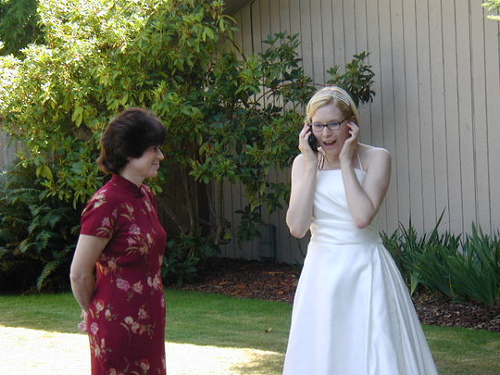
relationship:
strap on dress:
[350, 146, 367, 172] [282, 149, 447, 372]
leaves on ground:
[241, 264, 263, 280] [213, 267, 292, 299]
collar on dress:
[111, 176, 145, 195] [92, 185, 174, 273]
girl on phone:
[277, 84, 440, 375] [298, 113, 324, 156]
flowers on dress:
[122, 229, 142, 250] [74, 173, 176, 373]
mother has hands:
[69, 111, 170, 374] [74, 308, 93, 333]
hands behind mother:
[74, 308, 93, 333] [69, 111, 170, 374]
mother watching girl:
[69, 111, 187, 373] [277, 84, 440, 375]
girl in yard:
[277, 84, 440, 375] [0, 15, 408, 325]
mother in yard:
[69, 111, 170, 374] [0, 15, 408, 325]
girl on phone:
[277, 84, 440, 375] [301, 112, 322, 152]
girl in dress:
[277, 84, 440, 375] [282, 149, 447, 372]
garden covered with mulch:
[409, 228, 499, 299] [213, 258, 285, 297]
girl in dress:
[272, 100, 443, 373] [278, 166, 438, 373]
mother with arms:
[69, 111, 170, 374] [49, 220, 117, 336]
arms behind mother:
[49, 220, 117, 336] [69, 111, 170, 374]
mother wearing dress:
[69, 111, 170, 374] [77, 173, 171, 375]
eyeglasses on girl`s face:
[309, 117, 350, 133] [306, 100, 353, 154]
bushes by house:
[1, 157, 99, 312] [114, 10, 478, 286]